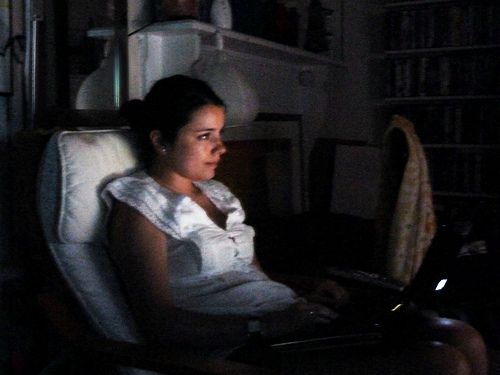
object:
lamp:
[190, 32, 260, 131]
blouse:
[100, 174, 299, 308]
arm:
[105, 203, 304, 337]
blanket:
[383, 114, 437, 287]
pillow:
[45, 132, 137, 245]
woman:
[101, 72, 359, 363]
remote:
[318, 262, 394, 297]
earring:
[160, 149, 166, 152]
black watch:
[246, 315, 266, 338]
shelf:
[358, 87, 497, 110]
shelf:
[414, 141, 499, 158]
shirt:
[95, 163, 303, 316]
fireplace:
[220, 135, 291, 247]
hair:
[120, 74, 224, 163]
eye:
[197, 134, 208, 141]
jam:
[136, 127, 172, 160]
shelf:
[175, 20, 320, 83]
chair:
[381, 113, 438, 284]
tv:
[497, 87, 498, 252]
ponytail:
[118, 98, 145, 126]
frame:
[252, 110, 304, 219]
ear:
[145, 130, 166, 153]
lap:
[227, 294, 473, 375]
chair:
[40, 126, 197, 372]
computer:
[249, 213, 470, 357]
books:
[376, 23, 496, 142]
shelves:
[373, 33, 500, 57]